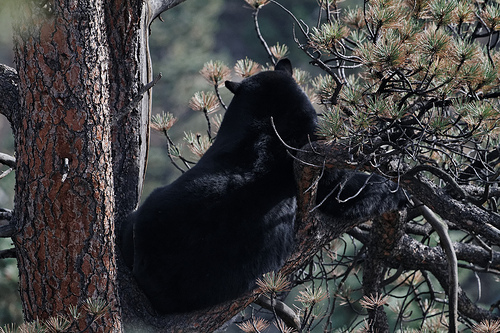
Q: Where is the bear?
A: In a tree.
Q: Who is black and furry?
A: The bear.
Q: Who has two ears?
A: A bear.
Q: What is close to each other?
A: Tree trunks.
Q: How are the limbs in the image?
A: Green and brown.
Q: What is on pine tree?
A: Branch.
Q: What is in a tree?
A: Bear.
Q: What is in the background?
A: Trees.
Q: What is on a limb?
A: Leg of the bear.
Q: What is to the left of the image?
A: Tree trucks.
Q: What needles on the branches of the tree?
A: Pine needles.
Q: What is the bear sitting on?
A: Branch.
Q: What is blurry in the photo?
A: Back trees.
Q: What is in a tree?
A: Black bear.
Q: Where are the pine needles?
A: In tree.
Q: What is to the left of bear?
A: Tree trunks.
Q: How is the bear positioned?
A: Laying down.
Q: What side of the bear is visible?
A: Back side.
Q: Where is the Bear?
A: In a tree.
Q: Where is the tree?
A: Forest.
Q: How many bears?
A: One.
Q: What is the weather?
A: Sunny.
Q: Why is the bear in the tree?
A: To sleep.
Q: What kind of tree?
A: Pinetree.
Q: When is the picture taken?
A: Day time.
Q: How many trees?
A: Two.